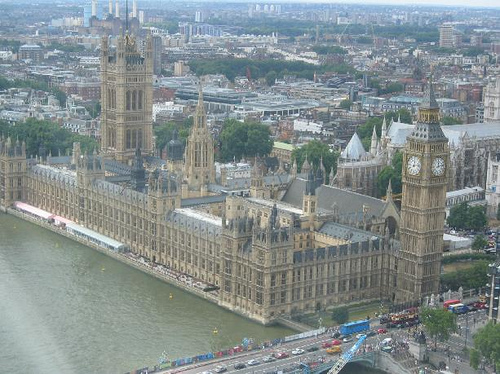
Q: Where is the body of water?
A: Left of the castle.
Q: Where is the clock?
A: On the right tower.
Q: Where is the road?
A: Right of the castle.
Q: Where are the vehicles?
A: On the road.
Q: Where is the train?
A: Left of the castle.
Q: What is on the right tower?
A: A clock.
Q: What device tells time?
A: The clock.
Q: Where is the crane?
A: By the road.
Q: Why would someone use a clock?
A: To tell time.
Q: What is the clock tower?
A: Big ben.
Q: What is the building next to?
A: Water.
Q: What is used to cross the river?
A: Bridge.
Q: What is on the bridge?
A: Cars.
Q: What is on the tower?
A: Clocks.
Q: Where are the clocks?
A: On the tower.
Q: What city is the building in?
A: London.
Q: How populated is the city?
A: Densely.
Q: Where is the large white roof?
A: Behind the clock tower.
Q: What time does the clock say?
A: Three o'clock.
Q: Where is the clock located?
A: Bell tower.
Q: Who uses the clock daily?
A: Everyone.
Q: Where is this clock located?
A: England.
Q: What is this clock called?
A: Big ben.